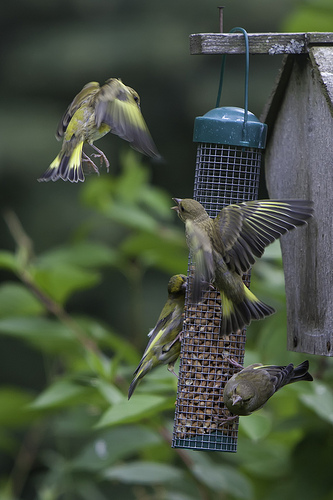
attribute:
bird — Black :
[227, 358, 316, 412]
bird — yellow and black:
[149, 181, 315, 297]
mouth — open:
[166, 191, 180, 211]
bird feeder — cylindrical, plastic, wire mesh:
[172, 103, 269, 467]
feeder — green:
[164, 102, 273, 447]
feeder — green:
[187, 32, 306, 156]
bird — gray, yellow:
[127, 268, 188, 399]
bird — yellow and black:
[169, 196, 314, 336]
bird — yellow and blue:
[38, 76, 162, 193]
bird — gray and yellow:
[30, 47, 164, 206]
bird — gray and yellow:
[157, 176, 320, 337]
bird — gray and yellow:
[107, 265, 204, 388]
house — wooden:
[266, 63, 331, 195]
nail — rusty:
[215, 3, 235, 27]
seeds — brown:
[174, 276, 243, 435]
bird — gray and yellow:
[216, 350, 314, 431]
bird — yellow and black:
[32, 71, 165, 189]